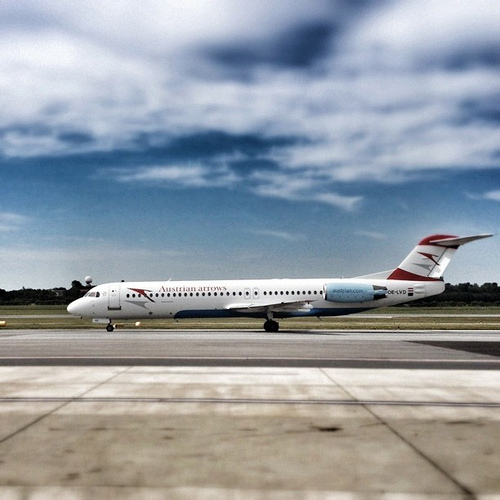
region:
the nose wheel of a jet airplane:
[101, 317, 116, 334]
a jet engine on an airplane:
[322, 275, 387, 312]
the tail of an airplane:
[380, 211, 480, 296]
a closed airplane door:
[95, 275, 121, 305]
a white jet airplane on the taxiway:
[52, 225, 488, 336]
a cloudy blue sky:
[2, 5, 487, 270]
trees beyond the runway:
[1, 276, 96, 311]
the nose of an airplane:
[60, 295, 81, 315]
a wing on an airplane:
[225, 296, 313, 312]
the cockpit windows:
[82, 289, 100, 299]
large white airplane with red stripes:
[63, 225, 498, 336]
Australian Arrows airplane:
[151, 279, 231, 296]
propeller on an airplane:
[319, 280, 390, 307]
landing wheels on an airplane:
[259, 314, 284, 334]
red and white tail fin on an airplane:
[380, 219, 498, 287]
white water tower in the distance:
[79, 271, 96, 287]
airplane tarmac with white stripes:
[23, 331, 116, 361]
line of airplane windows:
[151, 288, 321, 297]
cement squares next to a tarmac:
[31, 382, 416, 453]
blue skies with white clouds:
[102, 159, 299, 231]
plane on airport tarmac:
[65, 224, 482, 345]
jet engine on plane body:
[309, 273, 391, 320]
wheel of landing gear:
[254, 303, 301, 344]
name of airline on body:
[152, 279, 237, 299]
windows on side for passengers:
[157, 287, 242, 304]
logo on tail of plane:
[410, 241, 452, 274]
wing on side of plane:
[226, 290, 323, 319]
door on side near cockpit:
[99, 280, 133, 315]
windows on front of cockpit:
[79, 284, 112, 303]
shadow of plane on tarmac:
[284, 324, 374, 339]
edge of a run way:
[201, 402, 236, 427]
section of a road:
[256, 355, 274, 357]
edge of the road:
[36, 320, 57, 328]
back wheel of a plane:
[273, 322, 278, 323]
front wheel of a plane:
[106, 326, 116, 330]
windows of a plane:
[190, 291, 213, 292]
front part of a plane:
[72, 305, 84, 306]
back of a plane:
[419, 252, 426, 259]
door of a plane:
[115, 292, 120, 299]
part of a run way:
[211, 342, 270, 366]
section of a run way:
[146, 345, 171, 368]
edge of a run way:
[445, 335, 465, 361]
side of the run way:
[60, 348, 88, 361]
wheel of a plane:
[106, 322, 111, 333]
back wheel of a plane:
[266, 320, 276, 340]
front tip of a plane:
[69, 296, 75, 315]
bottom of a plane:
[180, 310, 195, 325]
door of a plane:
[112, 302, 127, 309]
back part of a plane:
[426, 270, 441, 300]